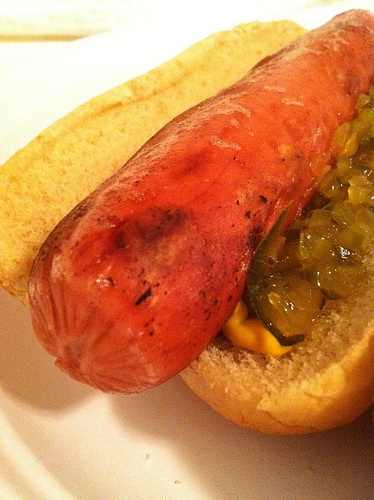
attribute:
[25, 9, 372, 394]
hotdog — cooked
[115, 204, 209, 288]
spot — black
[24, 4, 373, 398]
hot dog — yellow, cooked, on a bun, sitting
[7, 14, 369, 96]
plate — white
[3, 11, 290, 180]
bun — sitting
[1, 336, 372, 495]
plate — white, paper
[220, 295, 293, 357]
mustard — underneath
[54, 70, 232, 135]
bun — white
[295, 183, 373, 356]
relish — a piece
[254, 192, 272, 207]
spot — brunt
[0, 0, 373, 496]
plate — white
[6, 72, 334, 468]
hotdog — cooked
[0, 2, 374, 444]
hot dog — delicious looking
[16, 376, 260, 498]
plate — white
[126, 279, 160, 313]
spot — burnt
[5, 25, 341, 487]
plate — white